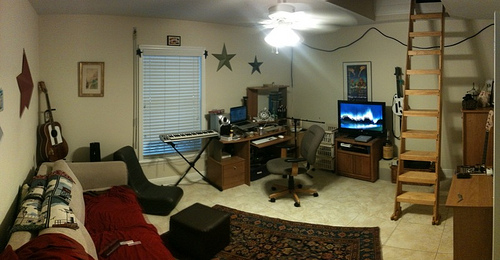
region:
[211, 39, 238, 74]
the star is onn the wall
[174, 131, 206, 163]
the keyboard is on a stand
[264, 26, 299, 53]
the light is on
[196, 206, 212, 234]
the ottoman is black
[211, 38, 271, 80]
gray metal stars on the wall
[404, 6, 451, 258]
a wooden ladder against the wall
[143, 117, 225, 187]
a keyboard on a stand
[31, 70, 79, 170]
a brown and white guitar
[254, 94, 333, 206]
an office chair with wheels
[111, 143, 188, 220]
a black gaming chair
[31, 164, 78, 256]
throw on the back of the couch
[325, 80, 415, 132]
a tv screen with trees and clouds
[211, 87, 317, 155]
computer on a wooden desk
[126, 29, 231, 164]
a window with blinds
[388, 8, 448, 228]
an attic ladder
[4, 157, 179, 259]
a couch in the room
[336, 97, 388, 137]
a television on the TV stand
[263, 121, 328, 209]
an office chair in the room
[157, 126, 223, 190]
a portable keyboard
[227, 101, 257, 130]
a laptop on the desk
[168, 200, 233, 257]
a black ottoman on the rug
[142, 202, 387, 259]
a rug in the room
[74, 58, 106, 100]
a picture on the wall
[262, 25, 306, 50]
a light on the ceiling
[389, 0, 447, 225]
a wooden ladder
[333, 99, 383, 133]
a flat screen TV that is powered on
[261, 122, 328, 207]
a tan colored computer chair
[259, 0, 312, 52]
bright lights on the ceiling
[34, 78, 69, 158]
a brown and white guitar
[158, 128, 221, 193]
a gray, white, and black keyboard on a black stand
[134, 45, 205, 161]
window covered with a window blind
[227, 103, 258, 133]
a laptop that is powered on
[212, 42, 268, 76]
a large star beside a small star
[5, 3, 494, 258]
a living room with furniture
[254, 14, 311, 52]
a light on a fan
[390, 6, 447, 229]
a ladder in the room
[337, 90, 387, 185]
a tv on a stand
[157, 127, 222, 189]
a keyboard on a stand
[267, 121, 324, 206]
a chair on wheels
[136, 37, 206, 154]
a window in the room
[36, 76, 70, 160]
a guitar on a stand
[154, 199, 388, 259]
a rug on the floor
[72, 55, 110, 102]
a picture on the wall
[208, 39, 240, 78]
Star on the wall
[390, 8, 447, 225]
Ladder made of wood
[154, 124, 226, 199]
Keyboard by a window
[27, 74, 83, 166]
Guitar in the corner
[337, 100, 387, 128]
Turned on television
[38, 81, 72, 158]
Dark wooden guitar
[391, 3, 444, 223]
Tall wooden ladder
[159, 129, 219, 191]
Gray paino next to window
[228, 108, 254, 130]
Gray laptop on desk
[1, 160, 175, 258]
Baige sofa next to guitar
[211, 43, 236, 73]
Star poster on the wall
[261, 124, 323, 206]
Cushioned computer chair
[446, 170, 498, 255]
Wooden desk next to ladder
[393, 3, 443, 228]
a wooden ladder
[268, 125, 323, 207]
a rolling desk chair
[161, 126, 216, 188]
a keyboard on a stand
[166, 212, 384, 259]
a floral area rug